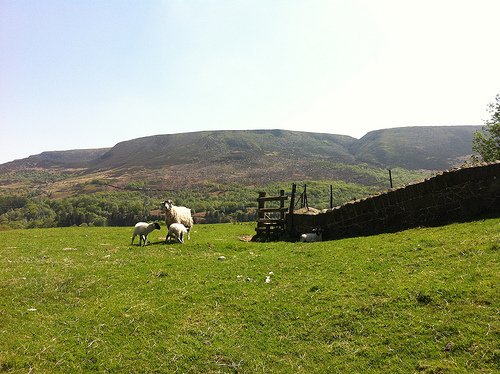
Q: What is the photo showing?
A: It is showing a pasture.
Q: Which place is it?
A: It is a pasture.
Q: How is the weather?
A: It is cloudy.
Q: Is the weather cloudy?
A: Yes, it is cloudy.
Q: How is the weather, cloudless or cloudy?
A: It is cloudy.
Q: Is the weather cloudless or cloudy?
A: It is cloudy.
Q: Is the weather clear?
A: No, it is cloudy.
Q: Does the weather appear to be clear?
A: No, it is cloudy.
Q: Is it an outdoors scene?
A: Yes, it is outdoors.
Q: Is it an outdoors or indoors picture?
A: It is outdoors.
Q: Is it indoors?
A: No, it is outdoors.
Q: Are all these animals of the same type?
A: Yes, all the animals are sheep.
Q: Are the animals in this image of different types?
A: No, all the animals are sheep.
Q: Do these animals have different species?
A: No, all the animals are sheep.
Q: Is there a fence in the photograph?
A: Yes, there is a fence.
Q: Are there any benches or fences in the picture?
A: Yes, there is a fence.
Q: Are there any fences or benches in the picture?
A: Yes, there is a fence.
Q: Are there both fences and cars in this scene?
A: No, there is a fence but no cars.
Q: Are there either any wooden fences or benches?
A: Yes, there is a wood fence.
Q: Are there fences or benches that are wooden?
A: Yes, the fence is wooden.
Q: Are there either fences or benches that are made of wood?
A: Yes, the fence is made of wood.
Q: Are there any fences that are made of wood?
A: Yes, there is a fence that is made of wood.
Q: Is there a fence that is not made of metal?
A: Yes, there is a fence that is made of wood.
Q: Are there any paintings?
A: No, there are no paintings.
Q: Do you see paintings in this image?
A: No, there are no paintings.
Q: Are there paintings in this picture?
A: No, there are no paintings.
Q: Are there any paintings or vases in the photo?
A: No, there are no paintings or vases.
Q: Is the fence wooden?
A: Yes, the fence is wooden.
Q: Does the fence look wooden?
A: Yes, the fence is wooden.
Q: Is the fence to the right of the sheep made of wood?
A: Yes, the fence is made of wood.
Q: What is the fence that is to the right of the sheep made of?
A: The fence is made of wood.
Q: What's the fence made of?
A: The fence is made of wood.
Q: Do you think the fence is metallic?
A: No, the fence is wooden.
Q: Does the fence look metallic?
A: No, the fence is wooden.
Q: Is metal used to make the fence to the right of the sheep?
A: No, the fence is made of wood.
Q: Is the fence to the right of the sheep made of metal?
A: No, the fence is made of wood.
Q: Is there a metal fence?
A: No, there is a fence but it is made of wood.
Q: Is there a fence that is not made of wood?
A: No, there is a fence but it is made of wood.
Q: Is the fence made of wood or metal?
A: The fence is made of wood.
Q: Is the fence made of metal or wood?
A: The fence is made of wood.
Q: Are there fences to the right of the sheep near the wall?
A: Yes, there is a fence to the right of the sheep.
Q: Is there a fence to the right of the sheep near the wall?
A: Yes, there is a fence to the right of the sheep.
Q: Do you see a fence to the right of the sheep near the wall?
A: Yes, there is a fence to the right of the sheep.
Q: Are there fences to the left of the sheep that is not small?
A: No, the fence is to the right of the sheep.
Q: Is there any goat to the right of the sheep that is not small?
A: No, there is a fence to the right of the sheep.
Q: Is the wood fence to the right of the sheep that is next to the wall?
A: Yes, the fence is to the right of the sheep.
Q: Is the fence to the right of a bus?
A: No, the fence is to the right of the sheep.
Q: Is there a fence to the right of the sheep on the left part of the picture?
A: Yes, there is a fence to the right of the sheep.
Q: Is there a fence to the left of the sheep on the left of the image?
A: No, the fence is to the right of the sheep.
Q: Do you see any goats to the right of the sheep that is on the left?
A: No, there is a fence to the right of the sheep.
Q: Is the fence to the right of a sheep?
A: Yes, the fence is to the right of a sheep.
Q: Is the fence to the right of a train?
A: No, the fence is to the right of a sheep.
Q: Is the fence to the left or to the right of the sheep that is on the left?
A: The fence is to the right of the sheep.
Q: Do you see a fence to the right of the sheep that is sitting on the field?
A: Yes, there is a fence to the right of the sheep.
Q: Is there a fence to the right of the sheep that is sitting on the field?
A: Yes, there is a fence to the right of the sheep.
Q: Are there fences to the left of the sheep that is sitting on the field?
A: No, the fence is to the right of the sheep.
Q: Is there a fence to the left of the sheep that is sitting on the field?
A: No, the fence is to the right of the sheep.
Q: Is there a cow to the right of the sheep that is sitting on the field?
A: No, there is a fence to the right of the sheep.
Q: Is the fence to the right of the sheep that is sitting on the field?
A: Yes, the fence is to the right of the sheep.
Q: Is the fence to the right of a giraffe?
A: No, the fence is to the right of the sheep.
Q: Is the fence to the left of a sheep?
A: No, the fence is to the right of a sheep.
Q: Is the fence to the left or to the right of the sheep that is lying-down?
A: The fence is to the right of the sheep.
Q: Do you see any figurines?
A: No, there are no figurines.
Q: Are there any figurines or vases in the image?
A: No, there are no figurines or vases.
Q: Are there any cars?
A: No, there are no cars.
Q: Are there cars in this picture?
A: No, there are no cars.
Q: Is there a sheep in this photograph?
A: Yes, there is a sheep.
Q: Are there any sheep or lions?
A: Yes, there is a sheep.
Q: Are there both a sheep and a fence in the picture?
A: Yes, there are both a sheep and a fence.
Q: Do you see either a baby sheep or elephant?
A: Yes, there is a baby sheep.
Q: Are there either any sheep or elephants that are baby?
A: Yes, the sheep is a baby.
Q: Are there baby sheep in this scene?
A: Yes, there is a baby sheep.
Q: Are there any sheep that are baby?
A: Yes, there is a baby sheep.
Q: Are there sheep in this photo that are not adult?
A: Yes, there is an baby sheep.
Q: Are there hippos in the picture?
A: No, there are no hippos.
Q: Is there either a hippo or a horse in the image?
A: No, there are no hippos or horses.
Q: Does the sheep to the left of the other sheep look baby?
A: Yes, the sheep is a baby.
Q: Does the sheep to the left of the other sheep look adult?
A: No, the sheep is a baby.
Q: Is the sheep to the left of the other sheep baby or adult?
A: The sheep is a baby.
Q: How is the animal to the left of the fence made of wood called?
A: The animal is a sheep.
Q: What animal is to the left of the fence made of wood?
A: The animal is a sheep.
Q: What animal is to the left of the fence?
A: The animal is a sheep.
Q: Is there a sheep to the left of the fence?
A: Yes, there is a sheep to the left of the fence.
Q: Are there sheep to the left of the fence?
A: Yes, there is a sheep to the left of the fence.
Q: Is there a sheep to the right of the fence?
A: No, the sheep is to the left of the fence.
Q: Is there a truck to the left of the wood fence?
A: No, there is a sheep to the left of the fence.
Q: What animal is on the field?
A: The animal is a sheep.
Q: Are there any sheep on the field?
A: Yes, there is a sheep on the field.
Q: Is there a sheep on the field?
A: Yes, there is a sheep on the field.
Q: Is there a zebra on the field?
A: No, there is a sheep on the field.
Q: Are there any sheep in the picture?
A: Yes, there is a sheep.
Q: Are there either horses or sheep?
A: Yes, there is a sheep.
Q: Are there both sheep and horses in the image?
A: No, there is a sheep but no horses.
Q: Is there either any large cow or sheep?
A: Yes, there is a large sheep.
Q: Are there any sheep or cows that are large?
A: Yes, the sheep is large.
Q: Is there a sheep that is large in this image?
A: Yes, there is a large sheep.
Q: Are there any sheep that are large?
A: Yes, there is a large sheep.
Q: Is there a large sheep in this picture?
A: Yes, there is a large sheep.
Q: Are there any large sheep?
A: Yes, there is a large sheep.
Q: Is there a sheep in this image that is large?
A: Yes, there is a sheep that is large.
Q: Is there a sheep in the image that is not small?
A: Yes, there is a large sheep.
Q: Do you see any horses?
A: No, there are no horses.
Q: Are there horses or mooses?
A: No, there are no horses or mooses.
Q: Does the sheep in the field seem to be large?
A: Yes, the sheep is large.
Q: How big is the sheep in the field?
A: The sheep is large.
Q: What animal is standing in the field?
A: The animal is a sheep.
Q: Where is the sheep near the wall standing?
A: The sheep is standing in the field.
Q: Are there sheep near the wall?
A: Yes, there is a sheep near the wall.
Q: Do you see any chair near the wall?
A: No, there is a sheep near the wall.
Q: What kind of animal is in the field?
A: The animal is a sheep.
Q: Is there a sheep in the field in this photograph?
A: Yes, there is a sheep in the field.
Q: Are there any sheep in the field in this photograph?
A: Yes, there is a sheep in the field.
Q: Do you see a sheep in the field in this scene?
A: Yes, there is a sheep in the field.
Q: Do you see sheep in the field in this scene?
A: Yes, there is a sheep in the field.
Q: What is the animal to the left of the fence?
A: The animal is a sheep.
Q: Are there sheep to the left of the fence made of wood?
A: Yes, there is a sheep to the left of the fence.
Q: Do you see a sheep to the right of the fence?
A: No, the sheep is to the left of the fence.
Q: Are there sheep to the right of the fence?
A: No, the sheep is to the left of the fence.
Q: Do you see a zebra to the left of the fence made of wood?
A: No, there is a sheep to the left of the fence.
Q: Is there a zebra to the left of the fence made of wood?
A: No, there is a sheep to the left of the fence.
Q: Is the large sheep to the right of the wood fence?
A: No, the sheep is to the left of the fence.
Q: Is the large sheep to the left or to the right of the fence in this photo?
A: The sheep is to the left of the fence.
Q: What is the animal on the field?
A: The animal is a sheep.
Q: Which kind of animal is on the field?
A: The animal is a sheep.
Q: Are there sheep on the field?
A: Yes, there is a sheep on the field.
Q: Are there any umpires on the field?
A: No, there is a sheep on the field.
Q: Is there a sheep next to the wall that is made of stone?
A: Yes, there is a sheep next to the wall.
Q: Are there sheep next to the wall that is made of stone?
A: Yes, there is a sheep next to the wall.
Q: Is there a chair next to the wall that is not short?
A: No, there is a sheep next to the wall.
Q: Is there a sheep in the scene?
A: Yes, there is a sheep.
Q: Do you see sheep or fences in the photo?
A: Yes, there is a sheep.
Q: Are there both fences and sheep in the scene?
A: Yes, there are both a sheep and a fence.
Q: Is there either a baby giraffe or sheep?
A: Yes, there is a baby sheep.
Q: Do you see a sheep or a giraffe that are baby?
A: Yes, the sheep is a baby.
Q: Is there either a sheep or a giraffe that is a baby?
A: Yes, the sheep is a baby.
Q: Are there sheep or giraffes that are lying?
A: Yes, the sheep is lying.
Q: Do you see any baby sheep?
A: Yes, there is a baby sheep.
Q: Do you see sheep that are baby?
A: Yes, there is a sheep that is a baby.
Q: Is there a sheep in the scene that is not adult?
A: Yes, there is an baby sheep.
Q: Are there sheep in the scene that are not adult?
A: Yes, there is an baby sheep.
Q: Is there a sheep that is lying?
A: Yes, there is a sheep that is lying.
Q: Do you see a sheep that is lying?
A: Yes, there is a sheep that is lying.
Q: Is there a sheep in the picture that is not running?
A: Yes, there is a sheep that is lying.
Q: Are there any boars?
A: No, there are no boars.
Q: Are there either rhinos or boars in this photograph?
A: No, there are no boars or rhinos.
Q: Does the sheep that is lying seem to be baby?
A: Yes, the sheep is a baby.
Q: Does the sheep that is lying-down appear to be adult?
A: No, the sheep is a baby.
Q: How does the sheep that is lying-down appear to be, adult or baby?
A: The sheep is a baby.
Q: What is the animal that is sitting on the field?
A: The animal is a sheep.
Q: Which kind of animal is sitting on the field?
A: The animal is a sheep.